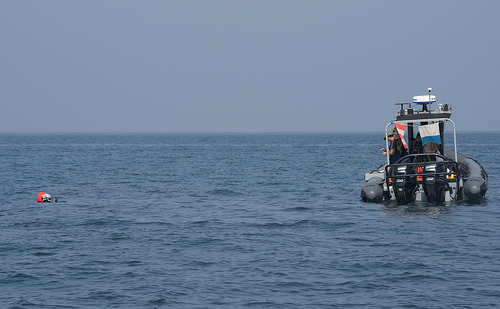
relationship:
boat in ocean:
[360, 88, 488, 203] [1, 132, 498, 308]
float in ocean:
[36, 192, 48, 202] [1, 132, 498, 308]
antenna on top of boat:
[412, 94, 434, 111] [360, 88, 488, 203]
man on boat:
[380, 133, 400, 161] [360, 88, 488, 203]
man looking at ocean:
[380, 133, 400, 161] [1, 132, 498, 308]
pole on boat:
[385, 117, 456, 161] [360, 88, 488, 203]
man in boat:
[380, 133, 400, 161] [360, 88, 488, 203]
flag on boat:
[391, 122, 406, 151] [360, 88, 488, 203]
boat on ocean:
[360, 88, 488, 203] [1, 132, 498, 308]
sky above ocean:
[1, 0, 499, 131] [1, 132, 498, 308]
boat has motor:
[360, 88, 488, 203] [390, 162, 443, 206]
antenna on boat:
[412, 94, 434, 111] [360, 88, 488, 203]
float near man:
[36, 192, 48, 202] [380, 133, 400, 161]